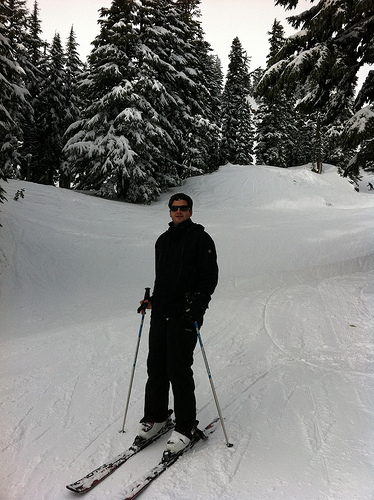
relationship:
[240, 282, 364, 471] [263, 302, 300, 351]
snow has groove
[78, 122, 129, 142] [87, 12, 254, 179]
snow on trees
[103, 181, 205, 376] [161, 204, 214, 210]
man wearing sunglasses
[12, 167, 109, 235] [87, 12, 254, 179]
path through trees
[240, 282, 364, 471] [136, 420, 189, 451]
snow on boots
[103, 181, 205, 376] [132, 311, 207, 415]
man wearing pants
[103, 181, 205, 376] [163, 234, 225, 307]
man wearing coat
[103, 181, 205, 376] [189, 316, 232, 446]
man holding ski pole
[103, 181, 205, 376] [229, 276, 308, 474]
man on slope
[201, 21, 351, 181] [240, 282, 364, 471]
evergreen covered in snow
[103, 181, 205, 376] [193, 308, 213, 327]
man wearing glove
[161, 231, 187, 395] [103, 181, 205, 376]
snow gear on man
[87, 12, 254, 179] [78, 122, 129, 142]
trees has snow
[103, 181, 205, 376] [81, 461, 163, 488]
man on skis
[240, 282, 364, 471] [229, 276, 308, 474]
snow on slope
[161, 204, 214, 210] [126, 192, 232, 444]
sunglasses on skier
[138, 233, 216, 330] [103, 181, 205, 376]
jacket on man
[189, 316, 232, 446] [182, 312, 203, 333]
ski pole in hand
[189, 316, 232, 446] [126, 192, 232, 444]
ski pole on skier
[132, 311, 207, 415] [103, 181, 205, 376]
pants on man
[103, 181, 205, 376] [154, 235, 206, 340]
man wearing black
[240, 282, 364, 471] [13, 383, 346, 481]
snow covers ground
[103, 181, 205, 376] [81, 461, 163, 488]
man wearing skis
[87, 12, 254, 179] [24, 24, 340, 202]
trees in background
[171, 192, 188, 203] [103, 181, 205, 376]
hair on man